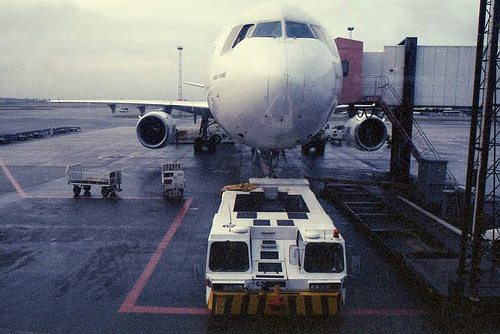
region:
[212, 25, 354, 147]
large white air plane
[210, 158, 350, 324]
white and yellow machine in front of plane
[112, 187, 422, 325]
black pavement with red lines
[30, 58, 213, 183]
left wing and engine of plane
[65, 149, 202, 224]
white luggage carts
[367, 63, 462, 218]
metal stairs next to plane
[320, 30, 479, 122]
passenger corridor on plane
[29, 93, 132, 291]
black asphalt runway by plane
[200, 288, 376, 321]
yellow and black paint on vehicle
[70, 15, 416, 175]
plane at an airport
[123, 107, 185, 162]
left engine of a plane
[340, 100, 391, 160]
right engine on a plane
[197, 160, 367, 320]
carrier truck at an airport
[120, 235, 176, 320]
red painted line on ground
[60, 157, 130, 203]
transporter on the ground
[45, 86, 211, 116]
wing on a plane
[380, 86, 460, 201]
stairs to a plane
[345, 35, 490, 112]
passenger transporter to a plane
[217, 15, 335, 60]
front windows of a plane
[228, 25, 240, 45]
window of a plane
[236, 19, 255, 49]
window of a plane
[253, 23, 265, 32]
window of a plane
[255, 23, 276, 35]
window of a plane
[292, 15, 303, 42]
window of a plane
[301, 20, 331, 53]
window of a plane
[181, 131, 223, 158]
wheel of a plane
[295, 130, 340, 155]
wheel of a plane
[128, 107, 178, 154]
turbine of a plane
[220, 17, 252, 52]
window of a plane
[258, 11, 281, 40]
window of a plane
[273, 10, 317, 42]
window of a plane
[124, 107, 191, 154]
engine of a plane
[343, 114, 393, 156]
engine of a plane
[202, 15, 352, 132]
front of a plane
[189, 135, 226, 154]
wheel of a plane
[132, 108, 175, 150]
the large engine of the plane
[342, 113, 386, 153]
the large engine of the plane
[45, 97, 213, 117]
the wing of the plane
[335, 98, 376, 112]
the wing of the plane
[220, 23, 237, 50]
the window of the plane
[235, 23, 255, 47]
the window of the plane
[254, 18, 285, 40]
the window of the plane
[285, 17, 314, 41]
the window of the plane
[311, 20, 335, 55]
the window of the plane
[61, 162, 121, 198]
the luggage cart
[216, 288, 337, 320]
yellow and black stripes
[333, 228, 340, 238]
orange security light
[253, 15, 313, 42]
the plane's front windsheild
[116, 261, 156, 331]
red line on the runway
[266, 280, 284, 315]
red fixture on the yellow stripes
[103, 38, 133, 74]
clouds in the sky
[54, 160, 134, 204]
luggage cart on the runway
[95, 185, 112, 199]
A tire on a vehicle.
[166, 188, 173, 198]
A tire on a vehicle.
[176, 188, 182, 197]
A tire on a vehicle.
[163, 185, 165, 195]
A tire on a vehicle.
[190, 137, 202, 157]
A tire on a vehicle.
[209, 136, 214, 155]
A tire on a vehicle.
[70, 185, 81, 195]
A tire on a vehicle.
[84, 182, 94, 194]
A tire on a vehicle.